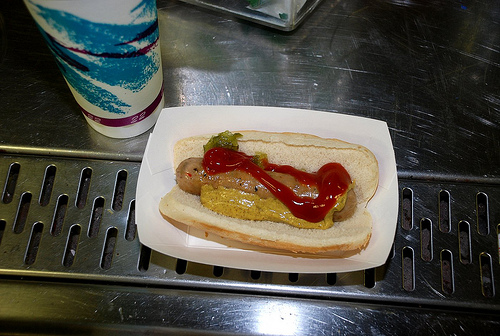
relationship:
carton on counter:
[134, 103, 402, 275] [0, 2, 499, 335]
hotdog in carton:
[175, 155, 358, 222] [134, 103, 402, 275]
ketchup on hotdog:
[203, 148, 351, 226] [175, 155, 358, 222]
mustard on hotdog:
[198, 182, 359, 234] [175, 155, 358, 222]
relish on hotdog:
[201, 128, 268, 171] [175, 155, 358, 222]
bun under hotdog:
[157, 130, 380, 256] [175, 155, 358, 222]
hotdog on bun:
[175, 155, 358, 222] [157, 130, 380, 256]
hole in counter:
[36, 163, 59, 209] [0, 2, 499, 335]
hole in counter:
[73, 167, 94, 212] [0, 2, 499, 335]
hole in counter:
[111, 166, 129, 213] [0, 2, 499, 335]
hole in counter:
[399, 186, 416, 233] [0, 2, 499, 335]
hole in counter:
[438, 186, 453, 234] [0, 2, 499, 335]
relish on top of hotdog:
[201, 128, 268, 171] [175, 155, 358, 222]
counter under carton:
[0, 2, 499, 335] [134, 103, 402, 275]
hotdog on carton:
[175, 155, 358, 222] [134, 103, 402, 275]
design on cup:
[30, 1, 162, 116] [24, 1, 165, 141]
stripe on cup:
[65, 81, 174, 130] [24, 1, 165, 141]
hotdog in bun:
[175, 155, 358, 222] [157, 130, 380, 256]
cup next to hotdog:
[24, 1, 165, 141] [175, 155, 358, 222]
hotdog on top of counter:
[175, 155, 358, 222] [0, 2, 499, 335]